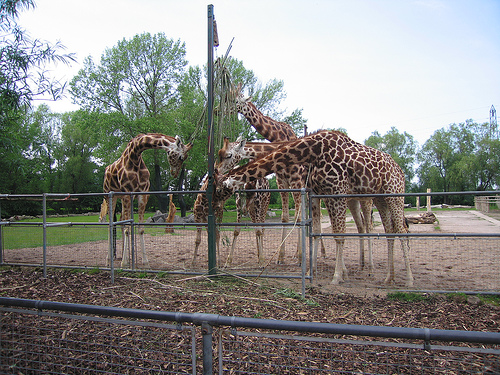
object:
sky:
[294, 5, 496, 112]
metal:
[2, 293, 498, 340]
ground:
[377, 202, 496, 246]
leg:
[192, 212, 203, 268]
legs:
[374, 201, 394, 286]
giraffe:
[213, 87, 350, 267]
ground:
[1, 265, 497, 373]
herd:
[92, 76, 417, 288]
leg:
[328, 190, 344, 285]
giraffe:
[214, 130, 414, 289]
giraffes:
[212, 131, 413, 288]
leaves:
[91, 38, 203, 106]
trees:
[416, 118, 500, 203]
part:
[358, 311, 369, 325]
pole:
[204, 5, 216, 272]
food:
[211, 68, 235, 122]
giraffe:
[103, 133, 194, 269]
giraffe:
[212, 134, 272, 266]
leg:
[390, 201, 414, 288]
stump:
[406, 211, 437, 224]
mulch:
[161, 290, 386, 355]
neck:
[245, 102, 277, 133]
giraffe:
[192, 146, 225, 271]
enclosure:
[2, 181, 498, 371]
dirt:
[2, 289, 453, 374]